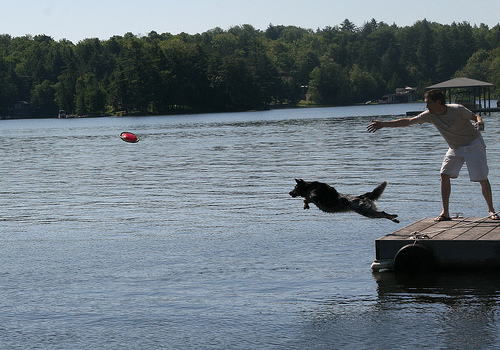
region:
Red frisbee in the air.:
[106, 123, 163, 153]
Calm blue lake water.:
[51, 180, 248, 286]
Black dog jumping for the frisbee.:
[251, 173, 411, 230]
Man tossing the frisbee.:
[359, 74, 496, 226]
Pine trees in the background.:
[246, 19, 480, 79]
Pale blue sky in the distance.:
[65, 6, 193, 28]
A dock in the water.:
[362, 209, 496, 281]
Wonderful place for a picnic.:
[417, 70, 492, 112]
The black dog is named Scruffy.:
[276, 170, 406, 227]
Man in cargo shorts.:
[426, 133, 491, 187]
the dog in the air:
[273, 169, 402, 238]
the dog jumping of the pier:
[271, 167, 430, 280]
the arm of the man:
[360, 90, 425, 151]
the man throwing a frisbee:
[365, 86, 497, 221]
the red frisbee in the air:
[116, 127, 142, 147]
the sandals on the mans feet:
[432, 206, 497, 226]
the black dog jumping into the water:
[285, 161, 407, 236]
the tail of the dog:
[369, 171, 389, 205]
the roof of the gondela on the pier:
[432, 76, 488, 89]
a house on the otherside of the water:
[383, 83, 420, 107]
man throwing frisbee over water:
[92, 83, 494, 155]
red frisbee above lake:
[95, 114, 169, 172]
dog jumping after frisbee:
[92, 126, 403, 233]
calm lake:
[30, 145, 278, 336]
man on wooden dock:
[370, 63, 498, 303]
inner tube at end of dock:
[379, 234, 479, 302]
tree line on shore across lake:
[2, 13, 497, 137]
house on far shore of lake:
[383, 71, 423, 166]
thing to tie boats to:
[448, 207, 471, 224]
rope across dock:
[420, 212, 499, 242]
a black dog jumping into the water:
[287, 175, 402, 225]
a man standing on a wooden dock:
[366, 88, 498, 224]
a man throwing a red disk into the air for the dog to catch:
[117, 88, 499, 234]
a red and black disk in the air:
[117, 130, 141, 144]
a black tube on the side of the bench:
[391, 244, 433, 275]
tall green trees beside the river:
[0, 18, 371, 107]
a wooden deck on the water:
[373, 215, 498, 266]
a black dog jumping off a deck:
[288, 174, 498, 243]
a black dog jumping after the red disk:
[116, 130, 403, 228]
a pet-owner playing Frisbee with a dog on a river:
[117, 88, 498, 223]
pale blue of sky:
[0, 0, 497, 42]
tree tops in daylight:
[0, 15, 497, 84]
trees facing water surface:
[0, 18, 499, 211]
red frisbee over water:
[89, 128, 192, 198]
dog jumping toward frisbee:
[117, 128, 399, 228]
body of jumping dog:
[289, 176, 397, 223]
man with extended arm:
[369, 87, 496, 220]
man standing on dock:
[374, 88, 496, 272]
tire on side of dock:
[375, 214, 495, 274]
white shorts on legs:
[439, 141, 496, 216]